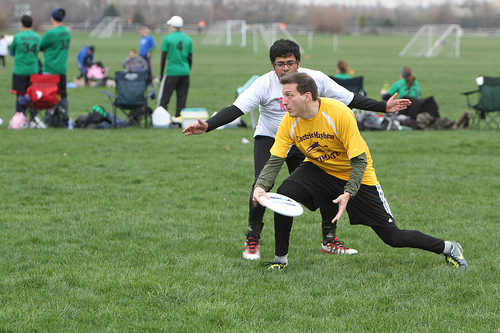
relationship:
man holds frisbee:
[251, 70, 472, 269] [252, 187, 312, 225]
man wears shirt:
[251, 70, 472, 269] [270, 93, 377, 187]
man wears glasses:
[178, 39, 411, 260] [272, 54, 297, 66]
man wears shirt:
[154, 15, 196, 123] [159, 29, 191, 79]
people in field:
[6, 5, 198, 123] [8, 42, 257, 152]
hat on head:
[162, 11, 185, 31] [168, 13, 182, 29]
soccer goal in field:
[393, 18, 465, 61] [302, 16, 498, 99]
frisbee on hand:
[254, 188, 303, 218] [246, 185, 264, 205]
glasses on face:
[273, 56, 296, 70] [272, 56, 299, 77]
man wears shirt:
[5, 14, 44, 127] [6, 27, 42, 77]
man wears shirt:
[40, 7, 73, 120] [39, 25, 73, 72]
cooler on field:
[177, 103, 209, 132] [0, 31, 499, 327]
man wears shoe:
[251, 70, 472, 272] [441, 234, 471, 272]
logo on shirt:
[302, 140, 343, 167] [270, 93, 377, 187]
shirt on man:
[270, 93, 377, 187] [251, 70, 472, 272]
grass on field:
[0, 27, 500, 329] [0, 22, 499, 327]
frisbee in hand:
[254, 188, 303, 218] [248, 185, 267, 206]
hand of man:
[248, 185, 267, 206] [251, 70, 472, 269]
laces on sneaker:
[242, 235, 263, 254] [242, 234, 264, 261]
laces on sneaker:
[327, 242, 347, 256] [316, 238, 356, 258]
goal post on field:
[393, 20, 433, 60] [0, 22, 499, 327]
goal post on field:
[456, 17, 463, 60] [0, 22, 499, 327]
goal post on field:
[456, 24, 463, 60] [0, 22, 499, 327]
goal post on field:
[423, 24, 435, 60] [0, 22, 499, 327]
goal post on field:
[222, 20, 237, 50] [0, 22, 499, 327]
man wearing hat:
[154, 24, 191, 120] [163, 14, 185, 28]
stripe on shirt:
[316, 106, 341, 141] [270, 93, 377, 187]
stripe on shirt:
[289, 118, 299, 141] [270, 93, 377, 187]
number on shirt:
[173, 39, 185, 55] [160, 27, 198, 79]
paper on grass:
[240, 129, 256, 148] [0, 27, 500, 329]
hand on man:
[248, 185, 267, 206] [251, 70, 472, 269]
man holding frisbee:
[251, 70, 472, 269] [254, 188, 303, 218]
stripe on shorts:
[374, 183, 394, 225] [278, 156, 398, 228]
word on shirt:
[294, 130, 344, 143] [270, 93, 377, 187]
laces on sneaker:
[327, 239, 346, 255] [316, 242, 357, 256]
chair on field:
[105, 55, 156, 128] [0, 22, 499, 327]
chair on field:
[17, 69, 67, 123] [0, 22, 499, 327]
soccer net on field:
[399, 16, 469, 62] [0, 22, 499, 327]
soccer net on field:
[192, 11, 308, 56] [0, 22, 499, 327]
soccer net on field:
[88, 14, 129, 41] [0, 22, 499, 327]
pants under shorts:
[272, 160, 450, 255] [276, 158, 396, 224]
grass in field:
[0, 27, 500, 329] [0, 22, 499, 327]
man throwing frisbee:
[251, 70, 472, 269] [257, 190, 303, 218]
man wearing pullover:
[251, 70, 472, 269] [268, 95, 379, 187]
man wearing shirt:
[178, 39, 411, 260] [227, 63, 357, 141]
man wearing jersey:
[40, 10, 73, 120] [41, 26, 69, 76]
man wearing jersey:
[4, 11, 48, 130] [6, 31, 36, 78]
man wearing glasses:
[178, 39, 411, 260] [276, 59, 300, 68]